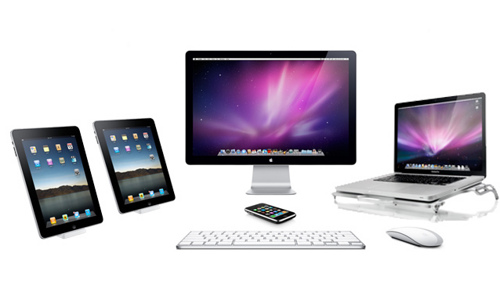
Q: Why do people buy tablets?
A: Tablets are easy to carry around.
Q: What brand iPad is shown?
A: An Apple iPad.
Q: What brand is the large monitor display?
A: Apple Cinema.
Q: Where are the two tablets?
A: On far left side.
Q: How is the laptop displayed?
A: On a vented shelf.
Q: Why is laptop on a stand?
A: To vent and stay cool.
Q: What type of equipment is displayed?
A: Electronic computing devices.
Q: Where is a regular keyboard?
A: In front of large monitor.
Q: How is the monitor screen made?
A: Flat screen.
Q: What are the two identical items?
A: Tablets.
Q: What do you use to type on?
A: Keyboard.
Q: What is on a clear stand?
A: Laptop.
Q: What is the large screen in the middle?
A: Computer monitor.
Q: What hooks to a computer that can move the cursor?
A: Mouse.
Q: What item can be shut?
A: Laptop.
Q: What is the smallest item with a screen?
A: Cell phone.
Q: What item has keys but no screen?
A: Keyboard.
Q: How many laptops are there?
A: One.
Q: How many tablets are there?
A: Two.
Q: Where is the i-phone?
A: Between the keyboard and monitor.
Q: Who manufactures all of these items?
A: Apple.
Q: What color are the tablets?
A: Black.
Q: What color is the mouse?
A: White.